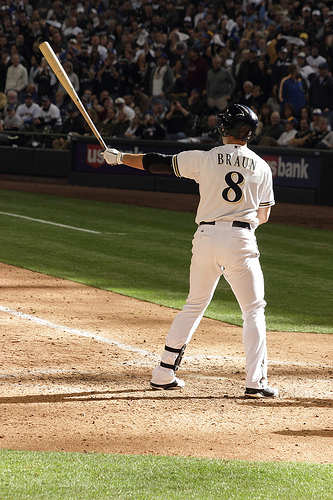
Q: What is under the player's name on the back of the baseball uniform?
A: Number.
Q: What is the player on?
A: A baseball field.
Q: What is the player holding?
A: A bat.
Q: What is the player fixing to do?
A: Hit a ball.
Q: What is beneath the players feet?
A: Dirt.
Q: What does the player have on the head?
A: A helmet.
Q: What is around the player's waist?
A: A belt.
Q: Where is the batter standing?
A: Batter's box.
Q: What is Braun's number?
A: Eight.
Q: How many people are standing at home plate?
A: One.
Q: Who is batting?
A: Braun.